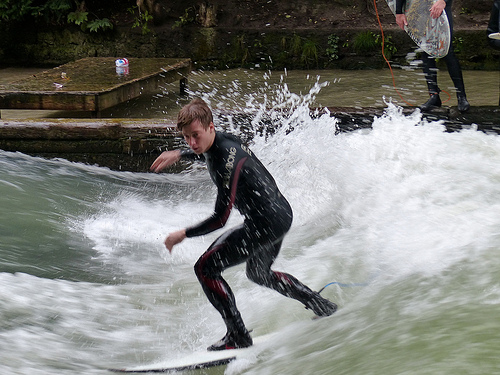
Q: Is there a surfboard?
A: Yes, there is a surfboard.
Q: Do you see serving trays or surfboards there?
A: Yes, there is a surfboard.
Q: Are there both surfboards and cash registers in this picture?
A: No, there is a surfboard but no cash registers.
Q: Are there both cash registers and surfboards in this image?
A: No, there is a surfboard but no cash registers.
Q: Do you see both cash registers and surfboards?
A: No, there is a surfboard but no cash registers.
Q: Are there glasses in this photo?
A: No, there are no glasses.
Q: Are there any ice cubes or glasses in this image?
A: No, there are no glasses or ice cubes.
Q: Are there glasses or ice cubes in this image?
A: No, there are no glasses or ice cubes.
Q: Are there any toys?
A: No, there are no toys.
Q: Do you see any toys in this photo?
A: No, there are no toys.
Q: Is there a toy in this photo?
A: No, there are no toys.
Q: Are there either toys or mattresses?
A: No, there are no toys or mattresses.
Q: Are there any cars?
A: No, there are no cars.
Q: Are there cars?
A: No, there are no cars.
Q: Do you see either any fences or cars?
A: No, there are no cars or fences.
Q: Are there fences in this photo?
A: No, there are no fences.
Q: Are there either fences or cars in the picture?
A: No, there are no fences or cars.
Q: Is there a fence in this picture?
A: No, there are no fences.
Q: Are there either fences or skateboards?
A: No, there are no fences or skateboards.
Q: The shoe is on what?
A: The shoe is on the surfboard.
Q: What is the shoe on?
A: The shoe is on the surfboard.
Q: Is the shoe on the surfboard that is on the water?
A: Yes, the shoe is on the surfboard.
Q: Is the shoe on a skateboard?
A: No, the shoe is on the surfboard.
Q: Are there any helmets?
A: No, there are no helmets.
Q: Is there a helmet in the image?
A: No, there are no helmets.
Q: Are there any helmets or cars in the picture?
A: No, there are no helmets or cars.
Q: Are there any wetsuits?
A: Yes, there is a wetsuit.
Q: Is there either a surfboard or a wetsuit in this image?
A: Yes, there is a wetsuit.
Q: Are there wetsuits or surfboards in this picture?
A: Yes, there is a wetsuit.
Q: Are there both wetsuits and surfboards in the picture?
A: Yes, there are both a wetsuit and a surfboard.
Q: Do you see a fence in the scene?
A: No, there are no fences.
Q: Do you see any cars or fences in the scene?
A: No, there are no fences or cars.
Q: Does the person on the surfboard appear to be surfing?
A: Yes, the person is surfing.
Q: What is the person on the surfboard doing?
A: The person is surfing.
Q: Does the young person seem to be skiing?
A: No, the person is surfing.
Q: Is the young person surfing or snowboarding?
A: The person is surfing.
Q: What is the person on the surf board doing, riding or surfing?
A: The person is surfing.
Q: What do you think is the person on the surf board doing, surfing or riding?
A: The person is surfing.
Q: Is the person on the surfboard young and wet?
A: Yes, the person is young and wet.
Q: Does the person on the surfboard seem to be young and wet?
A: Yes, the person is young and wet.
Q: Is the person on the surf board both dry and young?
A: No, the person is young but wet.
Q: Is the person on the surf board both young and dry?
A: No, the person is young but wet.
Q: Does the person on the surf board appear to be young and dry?
A: No, the person is young but wet.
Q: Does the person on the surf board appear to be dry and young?
A: No, the person is young but wet.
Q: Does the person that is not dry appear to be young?
A: Yes, the person is young.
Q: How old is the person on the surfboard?
A: The person is young.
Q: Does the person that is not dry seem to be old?
A: No, the person is young.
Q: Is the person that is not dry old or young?
A: The person is young.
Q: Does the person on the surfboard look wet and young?
A: Yes, the person is wet and young.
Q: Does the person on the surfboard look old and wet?
A: No, the person is wet but young.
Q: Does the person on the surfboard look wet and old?
A: No, the person is wet but young.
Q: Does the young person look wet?
A: Yes, the person is wet.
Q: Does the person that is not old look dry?
A: No, the person is wet.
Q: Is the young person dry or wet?
A: The person is wet.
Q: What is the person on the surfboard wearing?
A: The person is wearing a wetsuit.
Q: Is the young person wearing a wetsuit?
A: Yes, the person is wearing a wetsuit.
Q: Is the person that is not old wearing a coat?
A: No, the person is wearing a wetsuit.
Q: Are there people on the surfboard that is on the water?
A: Yes, there is a person on the surfboard.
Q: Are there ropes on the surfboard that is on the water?
A: No, there is a person on the surfboard.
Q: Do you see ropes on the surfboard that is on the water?
A: No, there is a person on the surfboard.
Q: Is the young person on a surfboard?
A: Yes, the person is on a surfboard.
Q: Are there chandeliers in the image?
A: No, there are no chandeliers.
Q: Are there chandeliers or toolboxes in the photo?
A: No, there are no chandeliers or toolboxes.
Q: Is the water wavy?
A: Yes, the water is wavy.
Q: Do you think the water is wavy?
A: Yes, the water is wavy.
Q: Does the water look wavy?
A: Yes, the water is wavy.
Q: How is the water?
A: The water is wavy.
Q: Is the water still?
A: No, the water is wavy.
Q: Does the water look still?
A: No, the water is wavy.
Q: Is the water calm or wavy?
A: The water is wavy.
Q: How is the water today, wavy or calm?
A: The water is wavy.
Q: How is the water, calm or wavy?
A: The water is wavy.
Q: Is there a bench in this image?
A: Yes, there is a bench.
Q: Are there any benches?
A: Yes, there is a bench.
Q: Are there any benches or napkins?
A: Yes, there is a bench.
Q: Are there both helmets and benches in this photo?
A: No, there is a bench but no helmets.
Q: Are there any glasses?
A: No, there are no glasses.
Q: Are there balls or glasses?
A: No, there are no glasses or balls.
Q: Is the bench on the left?
A: Yes, the bench is on the left of the image.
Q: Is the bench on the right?
A: No, the bench is on the left of the image.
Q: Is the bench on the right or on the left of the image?
A: The bench is on the left of the image.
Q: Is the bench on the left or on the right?
A: The bench is on the left of the image.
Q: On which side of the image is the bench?
A: The bench is on the left of the image.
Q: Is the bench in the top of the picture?
A: Yes, the bench is in the top of the image.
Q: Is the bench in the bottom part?
A: No, the bench is in the top of the image.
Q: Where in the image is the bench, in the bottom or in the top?
A: The bench is in the top of the image.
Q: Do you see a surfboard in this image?
A: Yes, there is a surfboard.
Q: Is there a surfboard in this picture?
A: Yes, there is a surfboard.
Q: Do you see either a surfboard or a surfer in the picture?
A: Yes, there is a surfboard.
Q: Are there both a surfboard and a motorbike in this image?
A: No, there is a surfboard but no motorcycles.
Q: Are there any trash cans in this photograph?
A: No, there are no trash cans.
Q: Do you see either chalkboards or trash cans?
A: No, there are no trash cans or chalkboards.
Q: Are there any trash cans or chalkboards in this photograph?
A: No, there are no trash cans or chalkboards.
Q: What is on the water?
A: The surfboard is on the water.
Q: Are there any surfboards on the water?
A: Yes, there is a surfboard on the water.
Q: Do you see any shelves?
A: No, there are no shelves.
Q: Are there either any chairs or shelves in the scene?
A: No, there are no shelves or chairs.